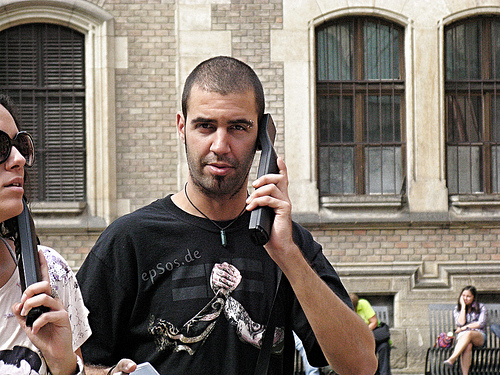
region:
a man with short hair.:
[167, 51, 274, 208]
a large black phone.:
[237, 106, 287, 238]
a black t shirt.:
[71, 205, 357, 372]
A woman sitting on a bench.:
[443, 277, 495, 374]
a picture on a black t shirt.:
[131, 223, 273, 374]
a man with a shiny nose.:
[206, 120, 233, 164]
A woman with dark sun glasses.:
[0, 90, 102, 372]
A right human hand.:
[246, 143, 380, 374]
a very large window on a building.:
[311, 16, 409, 202]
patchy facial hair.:
[184, 145, 254, 208]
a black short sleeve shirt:
[82, 193, 349, 374]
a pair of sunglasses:
[2, 128, 36, 168]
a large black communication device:
[249, 111, 276, 242]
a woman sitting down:
[437, 285, 484, 372]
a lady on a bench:
[424, 287, 499, 372]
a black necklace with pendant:
[180, 180, 253, 246]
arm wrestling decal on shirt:
[139, 247, 289, 357]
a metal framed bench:
[423, 300, 497, 373]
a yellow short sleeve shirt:
[349, 298, 374, 323]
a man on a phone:
[76, 55, 380, 374]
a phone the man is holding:
[253, 139, 283, 250]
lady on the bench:
[451, 290, 488, 363]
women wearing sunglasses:
[0, 130, 41, 160]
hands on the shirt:
[205, 258, 257, 305]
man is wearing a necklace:
[207, 208, 233, 250]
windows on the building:
[317, 30, 401, 210]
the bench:
[426, 304, 447, 321]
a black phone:
[16, 246, 47, 294]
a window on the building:
[10, 30, 87, 112]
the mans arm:
[283, 245, 350, 315]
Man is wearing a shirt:
[71, 200, 355, 372]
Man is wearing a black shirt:
[70, 191, 355, 373]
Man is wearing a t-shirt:
[72, 192, 357, 373]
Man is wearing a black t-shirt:
[71, 189, 359, 373]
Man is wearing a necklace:
[178, 180, 253, 247]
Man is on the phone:
[249, 107, 281, 245]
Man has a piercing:
[245, 117, 254, 130]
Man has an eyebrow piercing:
[245, 115, 257, 133]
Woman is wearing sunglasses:
[0, 124, 44, 174]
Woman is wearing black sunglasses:
[0, 123, 39, 173]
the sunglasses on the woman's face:
[0, 129, 35, 165]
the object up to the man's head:
[247, 112, 277, 248]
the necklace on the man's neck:
[184, 179, 249, 247]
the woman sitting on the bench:
[442, 286, 486, 374]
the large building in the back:
[0, 1, 498, 374]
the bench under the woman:
[422, 302, 498, 374]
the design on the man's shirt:
[140, 247, 285, 372]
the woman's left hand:
[12, 248, 72, 374]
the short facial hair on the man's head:
[182, 136, 258, 203]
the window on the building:
[312, 12, 406, 195]